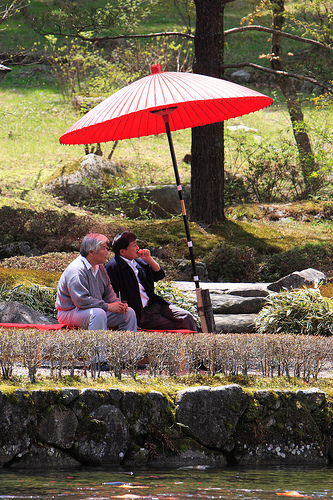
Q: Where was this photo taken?
A: Along the river.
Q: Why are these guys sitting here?
A: They are relaxing.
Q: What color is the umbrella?
A: Red.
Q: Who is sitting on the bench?
A: 2 men.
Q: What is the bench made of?
A: Wood.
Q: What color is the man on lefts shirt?
A: Gray.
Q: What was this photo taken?
A: Daytime.